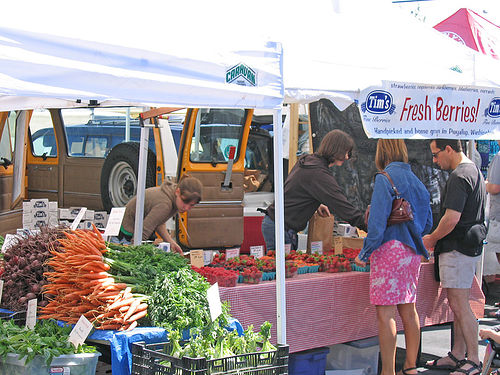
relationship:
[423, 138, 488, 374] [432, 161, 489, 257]
man in shirt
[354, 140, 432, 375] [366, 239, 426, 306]
woman in skirt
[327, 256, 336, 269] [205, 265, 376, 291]
berry on table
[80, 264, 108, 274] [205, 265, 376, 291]
carrot on table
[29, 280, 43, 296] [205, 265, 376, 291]
radish on table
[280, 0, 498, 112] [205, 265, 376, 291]
canopy over table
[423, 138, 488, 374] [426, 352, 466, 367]
man has sandal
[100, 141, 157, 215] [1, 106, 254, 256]
tire on van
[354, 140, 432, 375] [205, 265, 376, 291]
woman in front of table